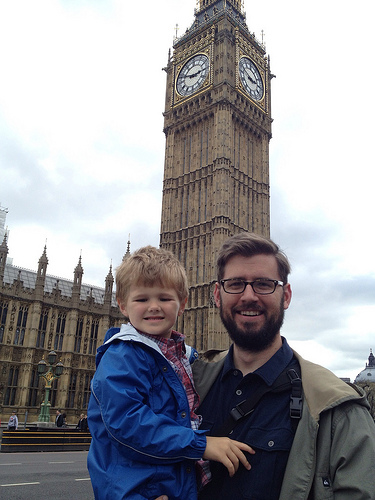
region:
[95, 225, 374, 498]
man holding young boy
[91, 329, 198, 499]
blue coat of boy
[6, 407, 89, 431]
people walking in front of building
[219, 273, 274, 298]
black framed glasses of man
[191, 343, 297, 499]
navy button up shirt of man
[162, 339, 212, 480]
red and white plaid shirt of boy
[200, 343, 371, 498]
coat man is wearing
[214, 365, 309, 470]
black straps of man's bag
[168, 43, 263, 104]
two clocks on clock tower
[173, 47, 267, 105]
black hands of the clock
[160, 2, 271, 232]
this is a tower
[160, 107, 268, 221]
the wall is brown in color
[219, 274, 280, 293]
the man is wearing specks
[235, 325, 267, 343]
the the man is bearded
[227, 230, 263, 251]
the hair is long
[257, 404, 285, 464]
the shirt is blue in color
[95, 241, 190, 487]
this is a child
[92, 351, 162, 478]
the jacket is blue in color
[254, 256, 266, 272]
the man is light skinned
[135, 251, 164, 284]
the hair is pale brown in color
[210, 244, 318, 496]
this is a man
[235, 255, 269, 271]
the man is light skinned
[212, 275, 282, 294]
this is a spectacle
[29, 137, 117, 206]
this is the sky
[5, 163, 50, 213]
the sky is blue in color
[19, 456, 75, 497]
this is the road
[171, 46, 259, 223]
this is a building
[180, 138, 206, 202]
this is the wall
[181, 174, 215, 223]
the wall is brown in color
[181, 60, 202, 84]
this is a clock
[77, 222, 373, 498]
Two peole in the foreground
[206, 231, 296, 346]
Man is wearing eyeglasses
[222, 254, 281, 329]
Man in the foreground is smiling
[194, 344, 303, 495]
Man is wearing a dark blue shirt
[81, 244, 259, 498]
A small boy in the foreground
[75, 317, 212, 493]
Young boy is wearing a blue jacket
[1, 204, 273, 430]
An old building in the background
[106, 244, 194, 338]
Young boy has blonde hair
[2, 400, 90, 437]
Three people in the background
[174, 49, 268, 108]
A clock on the building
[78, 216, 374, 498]
The man is holding a little boy.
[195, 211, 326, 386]
The man is wearing glasses.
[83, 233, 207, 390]
The boy has hair.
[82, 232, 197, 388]
The boy's hair is blonde.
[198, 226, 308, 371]
The man has a beard.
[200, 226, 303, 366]
The man has a moustache.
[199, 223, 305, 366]
The man has hair.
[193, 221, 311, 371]
The man's hair short.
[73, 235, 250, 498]
The boy is wearing a jacket.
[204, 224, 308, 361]
The man is smiling.